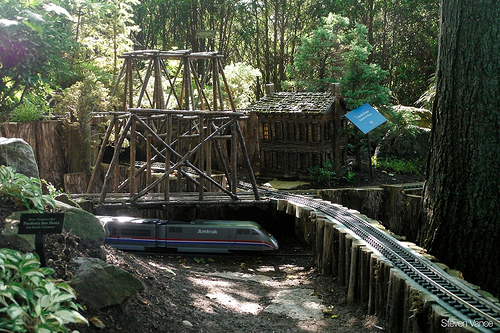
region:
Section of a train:
[192, 209, 284, 276]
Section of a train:
[146, 208, 223, 260]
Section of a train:
[110, 199, 175, 257]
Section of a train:
[81, 203, 146, 254]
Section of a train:
[170, 210, 240, 253]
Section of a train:
[219, 211, 281, 260]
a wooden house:
[256, 89, 339, 171]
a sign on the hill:
[17, 210, 67, 247]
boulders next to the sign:
[27, 171, 153, 312]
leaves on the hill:
[2, 245, 59, 322]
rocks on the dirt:
[171, 318, 203, 324]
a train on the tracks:
[98, 210, 275, 262]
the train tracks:
[269, 191, 466, 326]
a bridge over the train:
[93, 53, 265, 213]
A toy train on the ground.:
[97, 212, 279, 255]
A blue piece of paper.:
[344, 101, 386, 133]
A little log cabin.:
[256, 82, 342, 183]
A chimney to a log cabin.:
[331, 83, 343, 173]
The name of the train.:
[196, 227, 218, 235]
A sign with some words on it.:
[18, 213, 63, 265]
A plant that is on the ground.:
[0, 248, 89, 331]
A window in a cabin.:
[273, 119, 285, 139]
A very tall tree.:
[417, 9, 499, 298]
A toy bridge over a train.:
[68, 49, 270, 204]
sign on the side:
[340, 95, 386, 131]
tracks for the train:
[382, 240, 473, 295]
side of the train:
[100, 210, 292, 251]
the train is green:
[221, 217, 251, 239]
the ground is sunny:
[177, 265, 271, 320]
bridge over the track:
[105, 40, 263, 191]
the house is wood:
[235, 88, 339, 143]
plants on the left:
[12, 263, 58, 332]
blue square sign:
[341, 98, 391, 143]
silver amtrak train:
[95, 214, 289, 268]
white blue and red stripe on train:
[112, 231, 274, 250]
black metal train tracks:
[301, 183, 495, 328]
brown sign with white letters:
[12, 204, 69, 236]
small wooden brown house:
[250, 66, 367, 206]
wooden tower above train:
[85, 36, 268, 203]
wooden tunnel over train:
[70, 173, 414, 211]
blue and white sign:
[338, 90, 408, 156]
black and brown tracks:
[312, 201, 483, 331]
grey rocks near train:
[162, 252, 274, 317]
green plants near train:
[0, 176, 84, 321]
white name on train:
[188, 227, 241, 244]